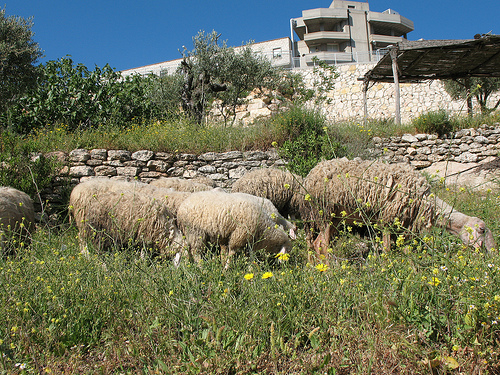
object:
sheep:
[176, 190, 296, 270]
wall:
[2, 123, 499, 205]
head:
[459, 215, 497, 254]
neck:
[431, 197, 467, 239]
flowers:
[261, 272, 273, 279]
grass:
[4, 239, 499, 373]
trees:
[187, 28, 266, 129]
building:
[92, 0, 415, 85]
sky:
[3, 2, 498, 78]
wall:
[207, 62, 500, 130]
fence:
[356, 31, 500, 138]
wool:
[291, 158, 432, 229]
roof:
[362, 35, 498, 85]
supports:
[389, 46, 402, 131]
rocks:
[129, 149, 153, 161]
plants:
[267, 321, 275, 359]